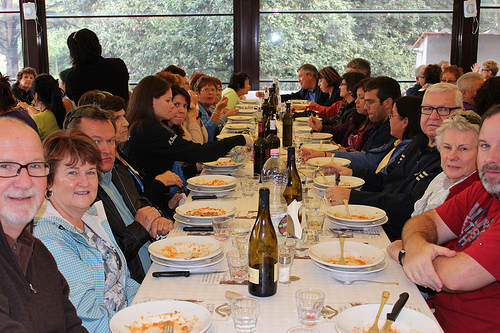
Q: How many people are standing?
A: One.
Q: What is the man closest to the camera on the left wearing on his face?
A: Glasses.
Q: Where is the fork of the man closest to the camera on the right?
A: To the left of his plate.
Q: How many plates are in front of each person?
A: Two.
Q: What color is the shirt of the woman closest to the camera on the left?
A: Blue and white.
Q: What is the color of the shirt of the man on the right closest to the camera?
A: Red.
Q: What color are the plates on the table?
A: White.